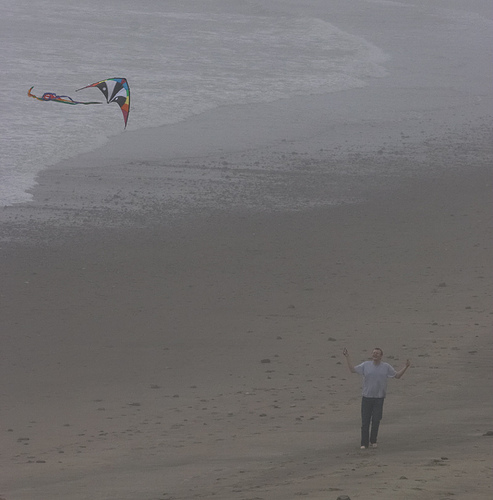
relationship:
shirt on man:
[354, 359, 397, 398] [343, 346, 410, 450]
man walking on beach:
[343, 346, 410, 450] [0, 2, 491, 497]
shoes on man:
[356, 440, 382, 450] [363, 349, 388, 444]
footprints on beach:
[16, 266, 489, 466] [0, 2, 491, 497]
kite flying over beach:
[35, 60, 188, 186] [1, 2, 441, 380]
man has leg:
[343, 346, 410, 450] [350, 409, 370, 448]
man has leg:
[343, 346, 410, 450] [368, 404, 384, 441]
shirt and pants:
[354, 359, 402, 396] [355, 391, 388, 443]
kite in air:
[28, 77, 130, 130] [206, 23, 416, 126]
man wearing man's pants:
[343, 346, 410, 450] [361, 397, 384, 445]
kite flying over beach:
[28, 77, 130, 130] [0, 2, 491, 497]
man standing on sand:
[343, 346, 410, 450] [4, 7, 492, 497]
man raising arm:
[343, 346, 410, 450] [385, 356, 410, 378]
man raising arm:
[343, 346, 410, 450] [341, 345, 362, 372]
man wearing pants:
[345, 346, 412, 448] [362, 393, 384, 444]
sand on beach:
[247, 353, 347, 418] [1, 0, 418, 346]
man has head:
[343, 346, 410, 450] [367, 343, 384, 362]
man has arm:
[343, 346, 410, 450] [339, 348, 355, 378]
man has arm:
[343, 346, 410, 450] [392, 354, 420, 378]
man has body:
[343, 346, 410, 450] [362, 359, 389, 397]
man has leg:
[343, 346, 410, 450] [359, 406, 370, 445]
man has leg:
[343, 346, 410, 450] [371, 409, 381, 442]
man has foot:
[343, 346, 410, 450] [358, 437, 367, 448]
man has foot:
[343, 346, 410, 450] [369, 433, 381, 450]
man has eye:
[343, 346, 410, 450] [373, 352, 379, 354]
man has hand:
[343, 346, 410, 450] [339, 346, 355, 360]